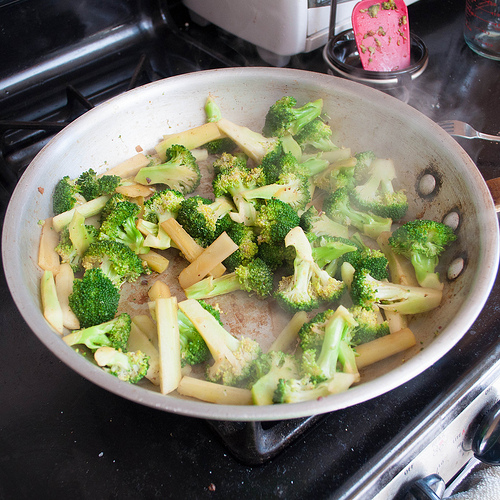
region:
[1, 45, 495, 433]
a pan over a tove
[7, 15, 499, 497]
a stove in a kitchen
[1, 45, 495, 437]
pan is color silver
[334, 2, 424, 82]
red spatula in a bowl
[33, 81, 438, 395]
broccoli and potatoes in a pan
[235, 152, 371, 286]
pieces of broccoli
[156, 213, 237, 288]
potato cut in slices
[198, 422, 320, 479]
part of a burner can be seen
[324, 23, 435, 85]
small black bowl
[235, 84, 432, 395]
steam can be seen coming out the pan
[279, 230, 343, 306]
Broccoli is being cooked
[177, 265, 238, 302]
Broccoli stem is light green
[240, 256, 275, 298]
Head of broccoli is dark green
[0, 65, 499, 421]
Pan is silver and round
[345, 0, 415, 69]
Small spatula is red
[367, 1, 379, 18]
Small broccoli piece of small red spatula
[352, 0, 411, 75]
Spatula in black mug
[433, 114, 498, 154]
Fork by pan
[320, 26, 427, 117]
Black mug by pan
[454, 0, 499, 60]
Glass measuring cup by black mug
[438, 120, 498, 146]
sterling silver fork on counter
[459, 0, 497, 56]
glass measuring cup on counter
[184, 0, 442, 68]
white toaster oven on counter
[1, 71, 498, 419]
silver skillet sitting on stove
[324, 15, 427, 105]
black cup sitting on counter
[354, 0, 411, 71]
red spatula sitting inside bowl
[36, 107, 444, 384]
florets and noodles laying in skillet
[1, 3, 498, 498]
black stove with black knobs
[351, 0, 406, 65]
food particles on red spatula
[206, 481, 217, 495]
small food crumb on stove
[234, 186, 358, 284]
broccoli sauteing in a pan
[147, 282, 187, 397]
bamboo shoot sauteing in the pan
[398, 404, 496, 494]
controls for the stove top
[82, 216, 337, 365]
broccoli and bamboo shoots cooking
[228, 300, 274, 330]
brown stuff left on bottom of pan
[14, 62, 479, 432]
silver wok on the stove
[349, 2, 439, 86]
utensil to stir vegetables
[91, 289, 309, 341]
pan of vegetables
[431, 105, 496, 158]
upside down fork on the counter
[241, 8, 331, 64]
edge of a white toaster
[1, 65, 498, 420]
frying pan with broccoli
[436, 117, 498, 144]
part of a silver fork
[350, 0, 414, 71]
bottom of a red spoon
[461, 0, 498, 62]
part of a measuring cup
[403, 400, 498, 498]
knobs on front of stove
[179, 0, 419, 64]
a white appliance on counter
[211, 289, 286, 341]
browning on bottom of pan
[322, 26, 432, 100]
a black spoon holder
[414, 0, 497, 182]
black counter top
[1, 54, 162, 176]
part of back burner